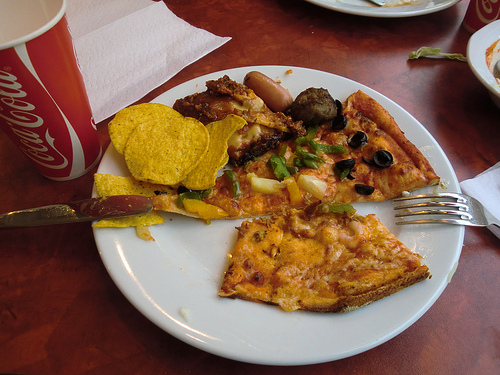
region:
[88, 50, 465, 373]
A white plate full of food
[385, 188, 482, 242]
a fork leaning on a white plate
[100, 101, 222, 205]
nacho chips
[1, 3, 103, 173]
a paper cup with a coca cola logo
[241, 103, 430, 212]
a slice of pizza with black olives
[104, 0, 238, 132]
a white napkin on the table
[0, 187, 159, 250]
a knife leaning on a plate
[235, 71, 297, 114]
a miniature hot dog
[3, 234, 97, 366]
a brown marble table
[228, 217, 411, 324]
a partially eaten slice of cheese pizza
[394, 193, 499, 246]
fork placed on the side of the plate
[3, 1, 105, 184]
the soda is in a paper cup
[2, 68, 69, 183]
Coco Cola is the logo on the side of the cup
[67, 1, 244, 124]
the napkin is white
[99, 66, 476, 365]
the plate with the food on it is white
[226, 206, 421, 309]
the pizza is a thin crust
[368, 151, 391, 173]
the pizza has olives on it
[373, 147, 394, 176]
the olive is black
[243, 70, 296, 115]
the hotdog is a miniture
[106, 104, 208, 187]
a nacho chip is on the side of the plate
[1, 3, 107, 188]
The red Coca-Cola cup on the table.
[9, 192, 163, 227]
The butter knife on the left side of the plate.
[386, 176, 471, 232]
The sporks of the fork on the right side of the plate.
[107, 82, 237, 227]
The nacho chips on the plate.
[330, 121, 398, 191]
The black olives on the pizza.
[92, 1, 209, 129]
The white napkin to the right of the Coca-Cola cup.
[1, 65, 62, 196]
The word Coca-Cola on the cup.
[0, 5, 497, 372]
The table the plate and cup are on.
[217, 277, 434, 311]
The crust of the cheese pizza.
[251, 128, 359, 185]
The green peppers on the pizza.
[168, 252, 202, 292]
part of a plate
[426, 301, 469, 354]
part of a table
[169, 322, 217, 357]
edge of a plate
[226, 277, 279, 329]
edge of a pizza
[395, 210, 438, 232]
edge of a fork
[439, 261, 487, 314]
part of a table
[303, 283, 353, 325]
part of a pizza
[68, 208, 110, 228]
edge of a kn ife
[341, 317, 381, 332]
part of a plate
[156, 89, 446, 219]
The pizza on the plate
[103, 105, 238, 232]
The chips on the plate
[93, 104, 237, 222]
The chips are yellow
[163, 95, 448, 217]
The pizza has olives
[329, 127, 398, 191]
The olives are black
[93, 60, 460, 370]
The plate is white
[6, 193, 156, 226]
The metal knife beside on the plate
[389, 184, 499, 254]
The metal fork on the plate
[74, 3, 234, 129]
The white napkin on the table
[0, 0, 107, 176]
The red and white cup next to the plate